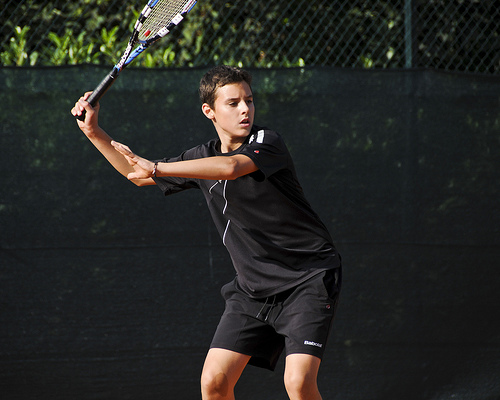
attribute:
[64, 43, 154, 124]
racket's handle — black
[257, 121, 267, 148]
stripe — white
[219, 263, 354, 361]
shorts — black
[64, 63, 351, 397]
man — young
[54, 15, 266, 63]
trees — green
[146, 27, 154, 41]
sticker — red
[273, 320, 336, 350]
letters — white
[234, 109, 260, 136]
mouth — open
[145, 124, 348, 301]
shirt — short sleeved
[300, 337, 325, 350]
logo — white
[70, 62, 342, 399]
boy — swinging, playing tennis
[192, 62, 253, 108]
hair — brown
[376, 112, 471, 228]
fence — chain link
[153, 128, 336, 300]
shirt — black, white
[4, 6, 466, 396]
fence — chain link